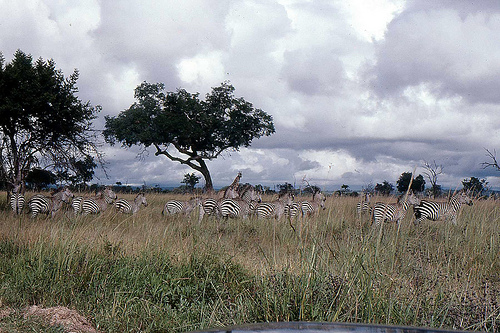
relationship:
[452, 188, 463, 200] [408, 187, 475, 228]
short mane on zebra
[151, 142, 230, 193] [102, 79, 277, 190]
trunk on tree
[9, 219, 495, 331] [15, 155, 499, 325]
grasses on plains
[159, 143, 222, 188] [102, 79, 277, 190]
trunk on tree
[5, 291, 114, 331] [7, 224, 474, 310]
rocks on grass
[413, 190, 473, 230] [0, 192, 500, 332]
zebra on field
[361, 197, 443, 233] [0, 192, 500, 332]
zebra on field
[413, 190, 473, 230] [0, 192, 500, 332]
zebra in field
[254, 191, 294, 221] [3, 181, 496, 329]
zebra in field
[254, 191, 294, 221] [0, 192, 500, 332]
zebra in field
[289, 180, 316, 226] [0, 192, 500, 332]
zebra in field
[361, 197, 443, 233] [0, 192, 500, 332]
zebra in field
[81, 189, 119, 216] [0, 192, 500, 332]
zebra in field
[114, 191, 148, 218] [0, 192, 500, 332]
white zebra in field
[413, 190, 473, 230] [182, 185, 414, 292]
zebra in field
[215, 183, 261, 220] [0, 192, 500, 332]
zebra in field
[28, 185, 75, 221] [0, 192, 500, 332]
zebra in field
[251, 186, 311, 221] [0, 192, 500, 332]
zebra in field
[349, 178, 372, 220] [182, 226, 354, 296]
zebra in field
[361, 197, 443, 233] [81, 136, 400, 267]
zebra in field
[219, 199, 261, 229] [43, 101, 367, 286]
zebra in field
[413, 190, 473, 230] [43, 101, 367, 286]
zebra in field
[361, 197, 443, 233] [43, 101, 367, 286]
zebra in field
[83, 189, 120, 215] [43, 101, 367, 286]
zebra in field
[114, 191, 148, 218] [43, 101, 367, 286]
white zebra in field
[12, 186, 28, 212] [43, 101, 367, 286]
zebra in field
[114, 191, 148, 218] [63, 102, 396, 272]
white zebra in field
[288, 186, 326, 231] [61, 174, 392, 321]
zebra in field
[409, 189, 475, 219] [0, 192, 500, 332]
zebra in field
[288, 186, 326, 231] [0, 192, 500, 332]
zebra in field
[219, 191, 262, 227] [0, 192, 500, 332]
zebra in field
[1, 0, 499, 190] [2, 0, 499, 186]
sky full of clouds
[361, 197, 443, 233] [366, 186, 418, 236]
zebra with baby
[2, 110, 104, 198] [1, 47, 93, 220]
branches hanging down tree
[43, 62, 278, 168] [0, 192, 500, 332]
tree in field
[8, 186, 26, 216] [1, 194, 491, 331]
zebra in grasses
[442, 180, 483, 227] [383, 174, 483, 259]
head of zebra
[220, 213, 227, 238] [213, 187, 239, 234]
leg of zebra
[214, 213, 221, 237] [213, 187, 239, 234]
leg of zebra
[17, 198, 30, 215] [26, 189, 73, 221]
tail of zebra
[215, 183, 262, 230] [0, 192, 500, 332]
zebra in field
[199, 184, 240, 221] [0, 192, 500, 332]
zebra in field